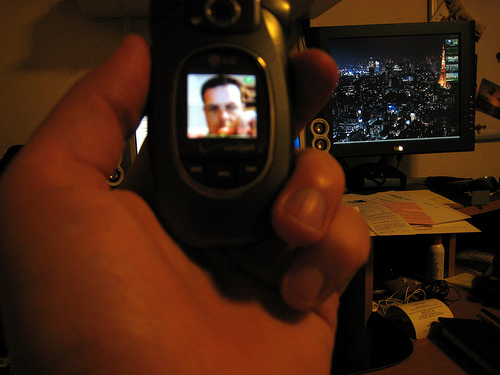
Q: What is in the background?
A: The television.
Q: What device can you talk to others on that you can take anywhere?
A: Cell phone.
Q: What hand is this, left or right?
A: Left.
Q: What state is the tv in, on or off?
A: It's on.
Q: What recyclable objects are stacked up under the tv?
A: Papers.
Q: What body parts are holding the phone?
A: Fingers.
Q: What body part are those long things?
A: Fingers.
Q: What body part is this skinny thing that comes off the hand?
A: Finger.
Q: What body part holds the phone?
A: Hand.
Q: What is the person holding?
A: Cell phone.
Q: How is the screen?
A: On.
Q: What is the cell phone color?
A: Grey.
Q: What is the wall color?
A: Brown.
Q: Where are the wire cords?
A: Floor.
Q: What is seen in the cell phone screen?
A: Photo of the person.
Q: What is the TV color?
A: Black.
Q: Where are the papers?
A: Table.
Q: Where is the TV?
A: Table.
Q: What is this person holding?
A: A cellphone.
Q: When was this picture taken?
A: At night.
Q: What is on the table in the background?
A: A TV.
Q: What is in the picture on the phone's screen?
A: A man.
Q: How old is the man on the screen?
A: Young.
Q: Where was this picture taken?
A: In a living room.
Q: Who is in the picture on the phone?
A: A young brunette man.